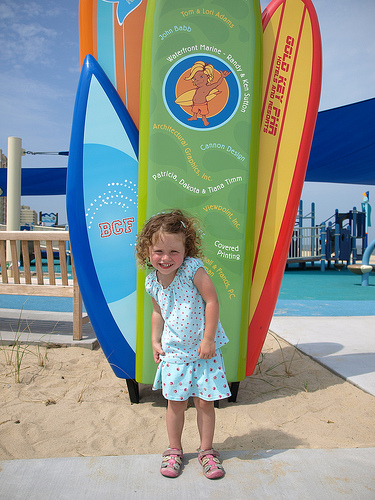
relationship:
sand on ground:
[0, 339, 373, 449] [3, 273, 373, 498]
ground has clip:
[264, 152, 303, 183] [178, 218, 188, 230]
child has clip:
[135, 207, 231, 478] [133, 209, 206, 270]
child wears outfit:
[135, 207, 231, 478] [161, 313, 205, 354]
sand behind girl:
[16, 356, 211, 486] [128, 214, 238, 494]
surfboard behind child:
[62, 53, 138, 375] [135, 207, 231, 478]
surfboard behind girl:
[132, 1, 263, 385] [135, 210, 230, 478]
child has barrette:
[135, 207, 231, 478] [176, 217, 189, 230]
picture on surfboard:
[159, 47, 246, 132] [132, 1, 263, 385]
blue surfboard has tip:
[53, 49, 197, 407] [71, 49, 111, 85]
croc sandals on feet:
[148, 443, 233, 478] [155, 443, 190, 483]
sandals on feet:
[197, 447, 232, 474] [200, 445, 229, 492]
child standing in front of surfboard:
[135, 207, 231, 478] [69, 52, 156, 354]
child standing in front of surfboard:
[135, 207, 231, 478] [135, 14, 265, 188]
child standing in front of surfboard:
[135, 207, 231, 478] [258, 5, 332, 376]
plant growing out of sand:
[247, 319, 308, 378] [280, 399, 349, 425]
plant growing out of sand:
[11, 316, 55, 381] [280, 399, 349, 425]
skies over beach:
[4, 30, 69, 134] [288, 249, 349, 271]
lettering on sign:
[156, 162, 246, 196] [135, 0, 263, 383]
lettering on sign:
[212, 235, 239, 262] [135, 0, 263, 383]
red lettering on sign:
[262, 34, 298, 139] [249, 0, 322, 387]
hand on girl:
[198, 336, 214, 358] [144, 218, 229, 478]